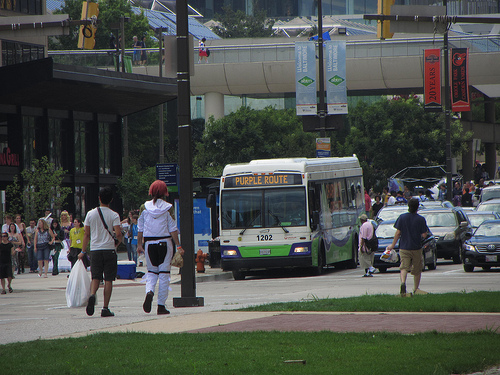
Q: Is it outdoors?
A: Yes, it is outdoors.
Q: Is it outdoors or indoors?
A: It is outdoors.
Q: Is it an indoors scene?
A: No, it is outdoors.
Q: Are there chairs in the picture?
A: No, there are no chairs.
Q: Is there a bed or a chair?
A: No, there are no chairs or beds.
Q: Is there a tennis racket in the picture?
A: No, there are no rackets.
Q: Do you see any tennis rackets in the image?
A: No, there are no tennis rackets.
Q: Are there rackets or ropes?
A: No, there are no rackets or ropes.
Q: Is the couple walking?
A: Yes, the couple is walking.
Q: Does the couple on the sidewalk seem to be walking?
A: Yes, the couple is walking.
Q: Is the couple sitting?
A: No, the couple is walking.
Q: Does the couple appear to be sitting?
A: No, the couple is walking.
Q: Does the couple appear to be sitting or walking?
A: The couple is walking.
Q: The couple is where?
A: The couple is on the sidewalk.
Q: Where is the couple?
A: The couple is on the sidewalk.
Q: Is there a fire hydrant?
A: Yes, there is a fire hydrant.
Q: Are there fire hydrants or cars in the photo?
A: Yes, there is a fire hydrant.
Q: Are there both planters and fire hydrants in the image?
A: No, there is a fire hydrant but no planters.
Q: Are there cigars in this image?
A: No, there are no cigars.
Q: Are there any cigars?
A: No, there are no cigars.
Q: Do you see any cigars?
A: No, there are no cigars.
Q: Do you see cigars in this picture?
A: No, there are no cigars.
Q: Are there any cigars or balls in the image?
A: No, there are no cigars or balls.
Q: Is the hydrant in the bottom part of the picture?
A: Yes, the hydrant is in the bottom of the image.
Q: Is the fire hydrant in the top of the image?
A: No, the fire hydrant is in the bottom of the image.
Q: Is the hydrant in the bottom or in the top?
A: The hydrant is in the bottom of the image.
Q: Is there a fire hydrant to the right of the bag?
A: Yes, there is a fire hydrant to the right of the bag.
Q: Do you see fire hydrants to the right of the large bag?
A: Yes, there is a fire hydrant to the right of the bag.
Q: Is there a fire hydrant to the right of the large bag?
A: Yes, there is a fire hydrant to the right of the bag.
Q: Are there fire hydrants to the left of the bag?
A: No, the fire hydrant is to the right of the bag.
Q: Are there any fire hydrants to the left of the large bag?
A: No, the fire hydrant is to the right of the bag.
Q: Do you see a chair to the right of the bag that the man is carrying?
A: No, there is a fire hydrant to the right of the bag.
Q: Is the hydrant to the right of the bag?
A: Yes, the hydrant is to the right of the bag.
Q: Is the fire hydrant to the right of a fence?
A: No, the fire hydrant is to the right of the bag.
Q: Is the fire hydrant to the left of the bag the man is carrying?
A: No, the fire hydrant is to the right of the bag.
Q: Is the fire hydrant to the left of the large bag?
A: No, the fire hydrant is to the right of the bag.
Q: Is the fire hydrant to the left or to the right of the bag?
A: The fire hydrant is to the right of the bag.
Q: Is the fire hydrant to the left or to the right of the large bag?
A: The fire hydrant is to the right of the bag.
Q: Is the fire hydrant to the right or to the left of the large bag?
A: The fire hydrant is to the right of the bag.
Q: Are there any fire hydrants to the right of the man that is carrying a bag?
A: Yes, there is a fire hydrant to the right of the man.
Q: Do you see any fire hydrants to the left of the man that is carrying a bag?
A: No, the fire hydrant is to the right of the man.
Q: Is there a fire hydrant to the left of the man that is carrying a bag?
A: No, the fire hydrant is to the right of the man.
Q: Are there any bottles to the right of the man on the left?
A: No, there is a fire hydrant to the right of the man.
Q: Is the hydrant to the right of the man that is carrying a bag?
A: Yes, the hydrant is to the right of the man.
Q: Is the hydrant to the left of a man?
A: No, the hydrant is to the right of a man.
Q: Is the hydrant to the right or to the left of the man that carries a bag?
A: The hydrant is to the right of the man.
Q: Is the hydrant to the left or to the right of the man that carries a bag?
A: The hydrant is to the right of the man.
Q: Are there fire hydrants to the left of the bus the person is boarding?
A: Yes, there is a fire hydrant to the left of the bus.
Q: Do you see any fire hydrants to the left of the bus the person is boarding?
A: Yes, there is a fire hydrant to the left of the bus.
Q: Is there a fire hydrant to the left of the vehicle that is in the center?
A: Yes, there is a fire hydrant to the left of the bus.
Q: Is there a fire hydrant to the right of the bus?
A: No, the fire hydrant is to the left of the bus.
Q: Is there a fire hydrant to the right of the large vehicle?
A: No, the fire hydrant is to the left of the bus.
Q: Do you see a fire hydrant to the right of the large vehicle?
A: No, the fire hydrant is to the left of the bus.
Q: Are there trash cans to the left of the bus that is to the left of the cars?
A: No, there is a fire hydrant to the left of the bus.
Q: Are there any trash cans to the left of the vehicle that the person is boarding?
A: No, there is a fire hydrant to the left of the bus.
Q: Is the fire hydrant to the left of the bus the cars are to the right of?
A: Yes, the fire hydrant is to the left of the bus.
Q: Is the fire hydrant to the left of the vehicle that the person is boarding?
A: Yes, the fire hydrant is to the left of the bus.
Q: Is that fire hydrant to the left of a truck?
A: No, the fire hydrant is to the left of the bus.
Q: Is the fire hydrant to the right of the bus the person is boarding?
A: No, the fire hydrant is to the left of the bus.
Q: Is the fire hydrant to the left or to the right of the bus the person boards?
A: The fire hydrant is to the left of the bus.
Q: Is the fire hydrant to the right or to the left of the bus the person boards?
A: The fire hydrant is to the left of the bus.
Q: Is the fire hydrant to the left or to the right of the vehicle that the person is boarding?
A: The fire hydrant is to the left of the bus.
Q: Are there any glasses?
A: No, there are no glasses.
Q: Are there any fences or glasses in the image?
A: No, there are no glasses or fences.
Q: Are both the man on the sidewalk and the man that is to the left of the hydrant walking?
A: Yes, both the man and the man are walking.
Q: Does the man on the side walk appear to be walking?
A: Yes, the man is walking.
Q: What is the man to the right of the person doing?
A: The man is walking.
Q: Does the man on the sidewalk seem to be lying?
A: No, the man is walking.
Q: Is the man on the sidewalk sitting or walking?
A: The man is walking.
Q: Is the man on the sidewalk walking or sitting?
A: The man is walking.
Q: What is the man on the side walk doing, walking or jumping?
A: The man is walking.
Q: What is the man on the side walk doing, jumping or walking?
A: The man is walking.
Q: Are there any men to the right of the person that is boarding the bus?
A: Yes, there is a man to the right of the person.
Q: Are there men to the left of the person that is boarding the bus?
A: No, the man is to the right of the person.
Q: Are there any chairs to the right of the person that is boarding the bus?
A: No, there is a man to the right of the person.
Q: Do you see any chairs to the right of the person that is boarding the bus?
A: No, there is a man to the right of the person.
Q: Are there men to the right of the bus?
A: Yes, there is a man to the right of the bus.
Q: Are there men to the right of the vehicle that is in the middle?
A: Yes, there is a man to the right of the bus.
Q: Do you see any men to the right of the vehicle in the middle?
A: Yes, there is a man to the right of the bus.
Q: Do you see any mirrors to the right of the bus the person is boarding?
A: No, there is a man to the right of the bus.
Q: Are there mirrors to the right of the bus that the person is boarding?
A: No, there is a man to the right of the bus.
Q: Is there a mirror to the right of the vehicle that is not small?
A: No, there is a man to the right of the bus.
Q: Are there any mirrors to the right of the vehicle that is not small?
A: No, there is a man to the right of the bus.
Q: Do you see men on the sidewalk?
A: Yes, there is a man on the sidewalk.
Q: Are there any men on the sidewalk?
A: Yes, there is a man on the sidewalk.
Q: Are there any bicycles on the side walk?
A: No, there is a man on the side walk.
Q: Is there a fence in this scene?
A: No, there are no fences.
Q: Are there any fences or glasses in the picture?
A: No, there are no fences or glasses.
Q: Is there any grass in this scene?
A: Yes, there is grass.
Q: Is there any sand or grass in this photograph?
A: Yes, there is grass.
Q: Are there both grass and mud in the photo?
A: No, there is grass but no mud.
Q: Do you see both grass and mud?
A: No, there is grass but no mud.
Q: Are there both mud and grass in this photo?
A: No, there is grass but no mud.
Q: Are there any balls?
A: No, there are no balls.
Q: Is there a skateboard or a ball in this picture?
A: No, there are no balls or skateboards.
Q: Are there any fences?
A: No, there are no fences.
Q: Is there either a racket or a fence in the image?
A: No, there are no fences or rackets.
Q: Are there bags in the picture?
A: Yes, there is a bag.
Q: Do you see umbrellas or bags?
A: Yes, there is a bag.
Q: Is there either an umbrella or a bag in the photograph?
A: Yes, there is a bag.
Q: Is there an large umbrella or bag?
A: Yes, there is a large bag.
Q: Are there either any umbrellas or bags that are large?
A: Yes, the bag is large.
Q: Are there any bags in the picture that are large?
A: Yes, there is a large bag.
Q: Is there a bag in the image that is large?
A: Yes, there is a bag that is large.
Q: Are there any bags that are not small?
A: Yes, there is a large bag.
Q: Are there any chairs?
A: No, there are no chairs.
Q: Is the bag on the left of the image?
A: Yes, the bag is on the left of the image.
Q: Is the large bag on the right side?
A: No, the bag is on the left of the image.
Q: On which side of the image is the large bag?
A: The bag is on the left of the image.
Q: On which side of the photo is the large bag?
A: The bag is on the left of the image.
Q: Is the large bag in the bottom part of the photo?
A: Yes, the bag is in the bottom of the image.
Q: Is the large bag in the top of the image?
A: No, the bag is in the bottom of the image.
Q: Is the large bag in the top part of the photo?
A: No, the bag is in the bottom of the image.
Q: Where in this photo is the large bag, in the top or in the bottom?
A: The bag is in the bottom of the image.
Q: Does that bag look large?
A: Yes, the bag is large.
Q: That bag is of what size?
A: The bag is large.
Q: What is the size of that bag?
A: The bag is large.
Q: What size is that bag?
A: The bag is large.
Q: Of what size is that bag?
A: The bag is large.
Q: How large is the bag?
A: The bag is large.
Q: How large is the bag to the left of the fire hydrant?
A: The bag is large.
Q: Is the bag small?
A: No, the bag is large.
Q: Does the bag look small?
A: No, the bag is large.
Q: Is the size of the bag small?
A: No, the bag is large.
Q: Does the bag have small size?
A: No, the bag is large.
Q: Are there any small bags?
A: No, there is a bag but it is large.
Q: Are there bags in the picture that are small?
A: No, there is a bag but it is large.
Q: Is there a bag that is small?
A: No, there is a bag but it is large.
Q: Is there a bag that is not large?
A: No, there is a bag but it is large.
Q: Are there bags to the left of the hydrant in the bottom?
A: Yes, there is a bag to the left of the hydrant.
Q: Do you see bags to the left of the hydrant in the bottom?
A: Yes, there is a bag to the left of the hydrant.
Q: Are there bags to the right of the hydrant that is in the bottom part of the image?
A: No, the bag is to the left of the fire hydrant.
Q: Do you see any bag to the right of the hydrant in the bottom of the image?
A: No, the bag is to the left of the fire hydrant.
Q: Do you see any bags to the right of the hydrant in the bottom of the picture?
A: No, the bag is to the left of the fire hydrant.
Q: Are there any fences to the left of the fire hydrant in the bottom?
A: No, there is a bag to the left of the fire hydrant.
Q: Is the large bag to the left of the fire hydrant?
A: Yes, the bag is to the left of the fire hydrant.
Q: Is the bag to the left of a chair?
A: No, the bag is to the left of the fire hydrant.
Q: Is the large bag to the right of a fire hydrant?
A: No, the bag is to the left of a fire hydrant.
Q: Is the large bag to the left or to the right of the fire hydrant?
A: The bag is to the left of the fire hydrant.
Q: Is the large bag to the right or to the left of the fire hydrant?
A: The bag is to the left of the fire hydrant.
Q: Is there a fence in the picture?
A: No, there are no fences.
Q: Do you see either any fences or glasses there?
A: No, there are no fences or glasses.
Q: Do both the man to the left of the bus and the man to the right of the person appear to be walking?
A: Yes, both the man and the man are walking.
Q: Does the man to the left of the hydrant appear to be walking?
A: Yes, the man is walking.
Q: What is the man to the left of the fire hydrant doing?
A: The man is walking.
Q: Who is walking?
A: The man is walking.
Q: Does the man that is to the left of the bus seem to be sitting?
A: No, the man is walking.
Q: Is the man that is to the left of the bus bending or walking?
A: The man is walking.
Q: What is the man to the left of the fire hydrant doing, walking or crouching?
A: The man is walking.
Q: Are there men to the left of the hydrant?
A: Yes, there is a man to the left of the hydrant.